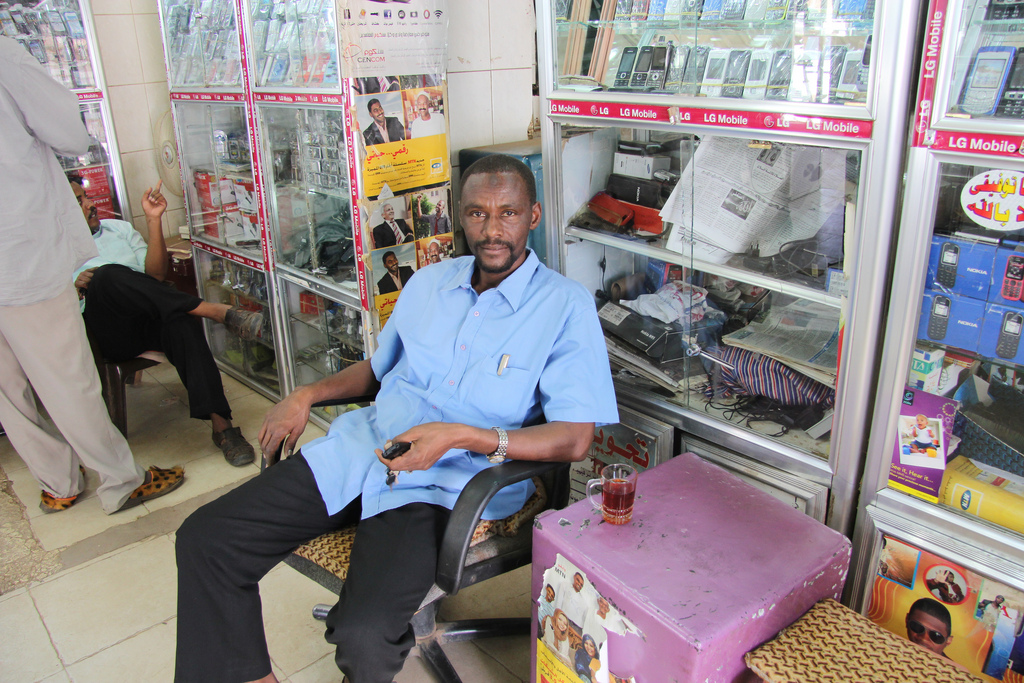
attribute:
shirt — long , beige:
[10, 42, 121, 292]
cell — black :
[369, 440, 417, 463]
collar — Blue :
[436, 251, 541, 315]